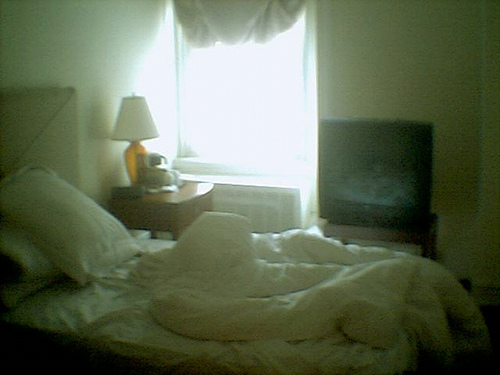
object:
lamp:
[110, 96, 159, 189]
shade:
[86, 91, 110, 138]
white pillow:
[0, 167, 146, 286]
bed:
[1, 232, 423, 373]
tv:
[318, 119, 434, 228]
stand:
[323, 214, 438, 265]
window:
[169, 0, 319, 183]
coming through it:
[169, 37, 316, 173]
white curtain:
[172, 1, 307, 49]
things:
[137, 152, 183, 193]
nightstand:
[108, 183, 214, 242]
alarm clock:
[111, 185, 146, 201]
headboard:
[0, 87, 95, 227]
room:
[0, 0, 490, 371]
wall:
[1, 2, 171, 243]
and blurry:
[141, 29, 343, 92]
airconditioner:
[179, 176, 302, 233]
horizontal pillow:
[0, 164, 132, 288]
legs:
[150, 229, 159, 240]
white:
[110, 94, 160, 141]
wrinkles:
[62, 289, 139, 333]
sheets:
[14, 238, 415, 375]